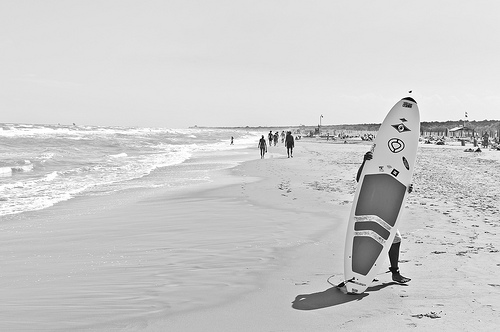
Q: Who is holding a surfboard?
A: A man.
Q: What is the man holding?
A: A surfboard.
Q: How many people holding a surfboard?
A: One.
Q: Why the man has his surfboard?
A: To surf.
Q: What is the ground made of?
A: Sand.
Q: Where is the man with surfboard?
A: At the beach.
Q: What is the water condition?
A: Wavy.